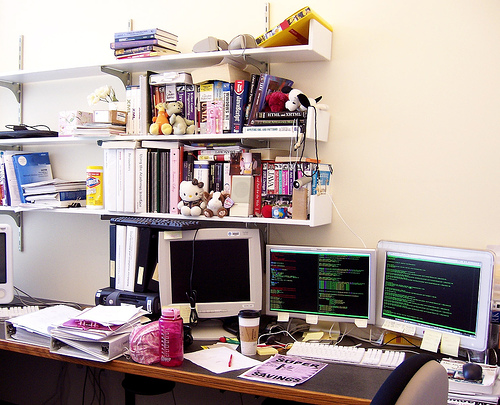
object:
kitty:
[175, 178, 208, 217]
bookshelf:
[0, 20, 333, 229]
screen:
[170, 239, 250, 306]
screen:
[267, 248, 369, 322]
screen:
[379, 251, 481, 340]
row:
[156, 228, 494, 354]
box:
[254, 6, 334, 50]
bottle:
[157, 306, 183, 367]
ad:
[237, 352, 327, 388]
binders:
[109, 224, 117, 291]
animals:
[163, 97, 196, 136]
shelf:
[0, 106, 330, 148]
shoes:
[0, 122, 59, 137]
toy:
[280, 88, 326, 114]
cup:
[236, 308, 262, 356]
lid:
[236, 309, 258, 318]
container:
[85, 165, 104, 210]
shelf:
[0, 192, 336, 228]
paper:
[237, 353, 327, 387]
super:
[275, 356, 320, 370]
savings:
[251, 369, 299, 382]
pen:
[227, 353, 233, 367]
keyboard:
[109, 217, 204, 232]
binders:
[132, 223, 157, 295]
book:
[253, 5, 336, 47]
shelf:
[0, 17, 332, 83]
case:
[129, 320, 162, 364]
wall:
[0, 0, 499, 307]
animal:
[198, 189, 235, 218]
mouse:
[460, 363, 481, 383]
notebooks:
[133, 147, 150, 215]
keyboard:
[282, 340, 406, 371]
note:
[435, 330, 458, 357]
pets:
[147, 102, 173, 136]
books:
[439, 357, 498, 396]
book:
[241, 124, 298, 134]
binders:
[170, 145, 181, 216]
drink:
[236, 308, 261, 358]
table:
[0, 296, 499, 404]